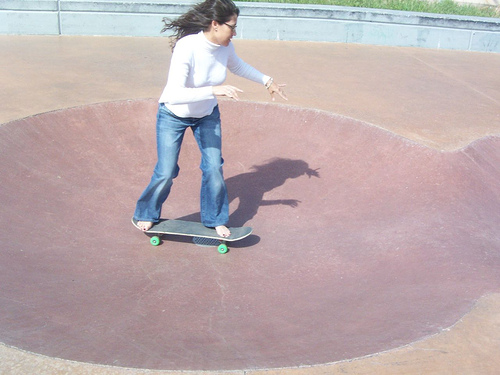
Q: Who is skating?
A: The girl.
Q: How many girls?
A: 1.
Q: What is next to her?
A: Shadow.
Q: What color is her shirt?
A: White.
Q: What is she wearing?
A: Jeans.